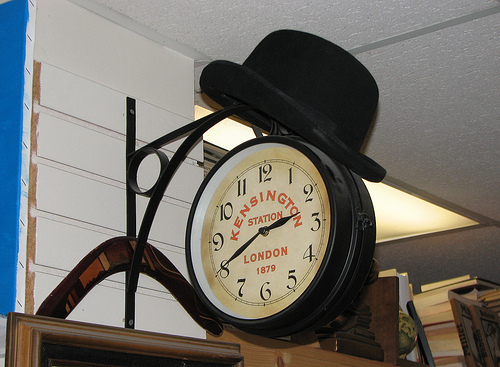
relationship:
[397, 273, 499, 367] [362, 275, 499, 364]
books on shelf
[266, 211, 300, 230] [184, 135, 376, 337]
hand on clock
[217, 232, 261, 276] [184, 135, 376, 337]
hand on clock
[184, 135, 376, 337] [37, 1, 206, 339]
clock attatched to wall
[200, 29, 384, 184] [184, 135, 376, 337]
hat on clock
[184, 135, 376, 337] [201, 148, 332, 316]
clock has face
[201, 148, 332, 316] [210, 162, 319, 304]
face has numbers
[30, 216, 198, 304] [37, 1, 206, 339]
panel on wall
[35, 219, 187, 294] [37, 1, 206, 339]
panel on wall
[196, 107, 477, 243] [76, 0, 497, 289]
light on ceiling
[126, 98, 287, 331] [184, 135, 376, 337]
pole holds clock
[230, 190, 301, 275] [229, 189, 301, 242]
letters says kensington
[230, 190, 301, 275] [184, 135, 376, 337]
letters on clock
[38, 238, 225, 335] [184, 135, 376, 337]
boomerang near clock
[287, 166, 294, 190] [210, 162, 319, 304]
1 in numbers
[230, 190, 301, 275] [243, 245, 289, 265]
letters say london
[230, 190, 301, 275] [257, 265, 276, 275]
letters say 1879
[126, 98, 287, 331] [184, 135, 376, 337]
pole supports clock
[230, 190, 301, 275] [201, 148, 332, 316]
letters on face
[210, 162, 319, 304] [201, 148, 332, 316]
numbers on face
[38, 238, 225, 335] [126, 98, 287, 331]
boomerang rests on pole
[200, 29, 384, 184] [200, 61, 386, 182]
hat has brim